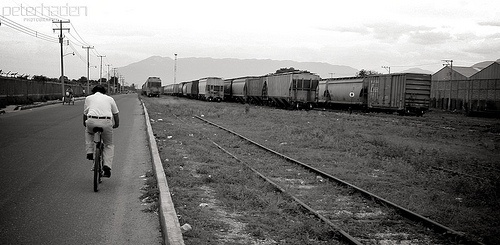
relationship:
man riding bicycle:
[62, 76, 121, 129] [90, 166, 108, 196]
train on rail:
[310, 73, 403, 117] [237, 116, 284, 173]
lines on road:
[32, 27, 49, 41] [24, 141, 32, 148]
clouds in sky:
[352, 2, 369, 6] [214, 5, 216, 6]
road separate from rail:
[24, 141, 32, 148] [237, 116, 284, 173]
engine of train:
[269, 85, 304, 107] [310, 73, 403, 117]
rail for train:
[237, 116, 284, 173] [310, 73, 403, 117]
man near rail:
[62, 76, 121, 129] [237, 116, 284, 173]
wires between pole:
[27, 13, 67, 32] [60, 59, 78, 74]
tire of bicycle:
[89, 174, 105, 191] [90, 166, 108, 196]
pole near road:
[60, 59, 78, 74] [24, 141, 32, 148]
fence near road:
[3, 84, 47, 112] [24, 141, 32, 148]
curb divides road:
[141, 93, 165, 153] [24, 141, 32, 148]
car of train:
[186, 91, 193, 95] [310, 73, 403, 117]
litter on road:
[339, 98, 466, 185] [24, 141, 32, 148]